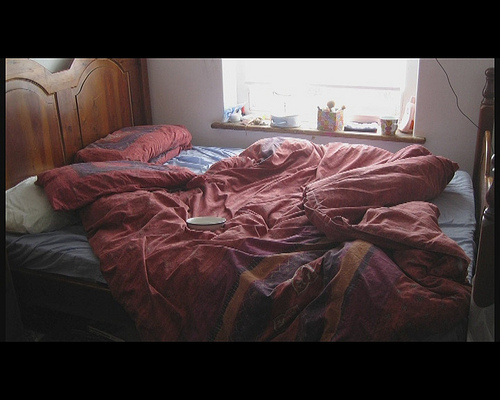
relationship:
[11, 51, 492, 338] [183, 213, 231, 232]
bed with bowl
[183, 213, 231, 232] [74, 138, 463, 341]
bowl on duvet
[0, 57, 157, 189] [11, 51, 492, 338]
headboard on bed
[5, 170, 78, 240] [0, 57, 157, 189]
pillow near headboard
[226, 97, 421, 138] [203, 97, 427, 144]
stuff on windowsill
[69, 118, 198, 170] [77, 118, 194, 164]
case with case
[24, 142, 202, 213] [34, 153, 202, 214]
case with case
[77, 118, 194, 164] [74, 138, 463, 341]
case matches duvet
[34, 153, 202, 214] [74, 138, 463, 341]
case matches duvet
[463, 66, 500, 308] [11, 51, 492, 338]
frame at bed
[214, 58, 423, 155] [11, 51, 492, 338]
window next to bed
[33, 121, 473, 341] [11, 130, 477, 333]
bedspread on mattress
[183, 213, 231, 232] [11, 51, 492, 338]
bowl on bed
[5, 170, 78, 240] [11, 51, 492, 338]
pillow on bed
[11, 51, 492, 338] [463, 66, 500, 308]
bed has foot board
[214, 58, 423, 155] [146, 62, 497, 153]
window on side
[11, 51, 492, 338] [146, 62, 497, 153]
bed has side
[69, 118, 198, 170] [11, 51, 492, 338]
case on bed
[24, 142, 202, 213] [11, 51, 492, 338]
case on bed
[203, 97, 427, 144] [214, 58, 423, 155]
windowsill by window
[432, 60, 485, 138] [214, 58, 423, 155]
wire hanging by window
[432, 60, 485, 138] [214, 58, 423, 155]
wire by window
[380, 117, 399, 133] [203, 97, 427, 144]
mug on windowsill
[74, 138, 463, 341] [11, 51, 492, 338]
quilt on bed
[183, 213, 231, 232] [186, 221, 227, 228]
bowl with rim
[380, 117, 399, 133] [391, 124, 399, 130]
cup with handle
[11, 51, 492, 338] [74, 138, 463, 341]
bed with blankets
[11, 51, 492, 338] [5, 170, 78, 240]
bed with pillow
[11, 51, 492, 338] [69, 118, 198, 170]
bed with case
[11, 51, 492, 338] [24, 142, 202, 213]
bed with case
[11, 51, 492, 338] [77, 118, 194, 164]
bed with pillowcase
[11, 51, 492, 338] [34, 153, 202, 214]
bed with pillowcase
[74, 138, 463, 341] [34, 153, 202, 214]
blankets match pillowcase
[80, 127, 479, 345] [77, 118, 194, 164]
blankets match pillowcase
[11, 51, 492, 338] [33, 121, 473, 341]
bed with bedspread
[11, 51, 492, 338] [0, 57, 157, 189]
bed with headboard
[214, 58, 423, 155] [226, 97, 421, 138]
window has items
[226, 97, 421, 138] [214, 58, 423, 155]
items on window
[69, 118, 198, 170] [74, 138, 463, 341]
case matches comforter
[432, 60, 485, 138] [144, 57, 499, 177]
wire on wall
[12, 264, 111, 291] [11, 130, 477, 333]
line on mattress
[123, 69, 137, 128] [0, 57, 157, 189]
stripe on head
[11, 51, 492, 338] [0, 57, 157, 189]
bed has head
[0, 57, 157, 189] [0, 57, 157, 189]
headboard on head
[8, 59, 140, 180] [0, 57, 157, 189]
pattern on head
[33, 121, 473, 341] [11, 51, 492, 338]
bedspread on bed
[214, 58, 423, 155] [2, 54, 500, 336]
window in bedroom